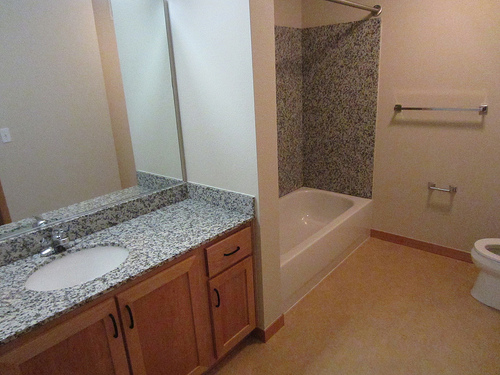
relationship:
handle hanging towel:
[394, 104, 488, 115] [397, 87, 477, 148]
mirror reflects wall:
[9, 10, 192, 230] [61, 8, 158, 162]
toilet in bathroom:
[469, 232, 498, 312] [3, 0, 493, 374]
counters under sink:
[16, 243, 274, 370] [21, 239, 151, 301]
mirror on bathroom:
[0, 0, 186, 239] [0, 0, 500, 375]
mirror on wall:
[0, 0, 186, 239] [155, 13, 244, 206]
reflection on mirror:
[33, 215, 48, 225] [0, 0, 186, 239]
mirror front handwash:
[0, 0, 186, 239] [75, 25, 246, 210]